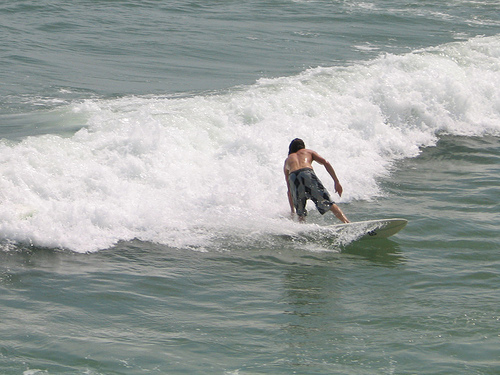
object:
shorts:
[287, 168, 334, 217]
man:
[284, 136, 353, 228]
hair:
[288, 138, 306, 154]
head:
[287, 138, 306, 154]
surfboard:
[328, 215, 411, 240]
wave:
[30, 108, 193, 230]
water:
[20, 8, 178, 59]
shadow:
[343, 244, 408, 279]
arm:
[315, 155, 342, 182]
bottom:
[333, 223, 402, 239]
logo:
[367, 229, 378, 237]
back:
[281, 138, 350, 225]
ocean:
[0, 0, 497, 132]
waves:
[325, 53, 485, 122]